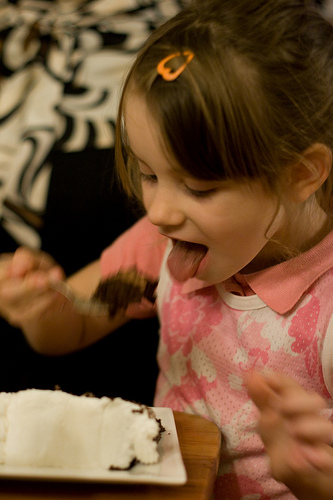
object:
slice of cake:
[4, 398, 149, 473]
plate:
[0, 406, 188, 486]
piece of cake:
[90, 266, 159, 320]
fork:
[49, 275, 116, 319]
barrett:
[156, 51, 195, 81]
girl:
[0, 7, 333, 500]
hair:
[114, 1, 333, 286]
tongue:
[165, 241, 207, 284]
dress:
[100, 214, 332, 500]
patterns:
[173, 318, 236, 405]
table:
[1, 409, 221, 500]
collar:
[243, 230, 333, 315]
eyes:
[138, 160, 230, 202]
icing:
[26, 415, 81, 453]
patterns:
[19, 10, 101, 113]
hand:
[0, 248, 67, 328]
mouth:
[156, 230, 212, 278]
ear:
[292, 142, 332, 203]